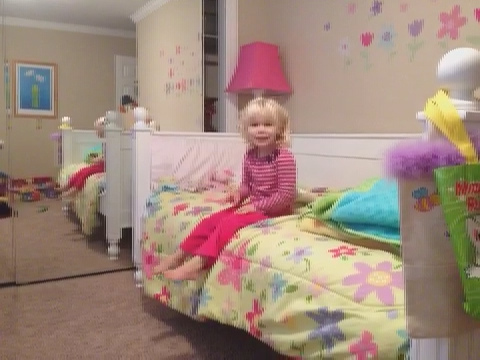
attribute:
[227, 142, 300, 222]
shirt — pink, striped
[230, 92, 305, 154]
hair — blond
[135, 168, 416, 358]
blanket — yellow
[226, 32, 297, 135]
lamp — pink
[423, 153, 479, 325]
bag — green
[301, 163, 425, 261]
blanket — blue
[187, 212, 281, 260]
pants — pink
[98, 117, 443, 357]
bed — white, framed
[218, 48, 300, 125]
lamp — pink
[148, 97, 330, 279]
girl — little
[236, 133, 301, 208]
shirt — pink, striped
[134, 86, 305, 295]
girl — little, blonde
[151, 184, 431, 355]
comforter — yellow, floral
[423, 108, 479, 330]
bag — green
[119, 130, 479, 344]
bed — white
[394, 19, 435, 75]
flower — purple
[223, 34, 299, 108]
lampshade — pink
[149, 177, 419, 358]
bedspread — yellow 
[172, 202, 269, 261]
pants — pink 